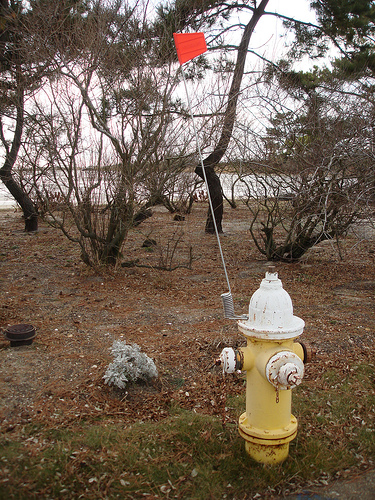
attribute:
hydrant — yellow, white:
[213, 265, 312, 464]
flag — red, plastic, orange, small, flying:
[170, 30, 237, 320]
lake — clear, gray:
[0, 166, 356, 211]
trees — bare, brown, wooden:
[1, 1, 372, 272]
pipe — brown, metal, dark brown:
[4, 324, 38, 346]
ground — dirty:
[0, 193, 373, 500]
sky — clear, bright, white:
[1, 3, 374, 170]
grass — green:
[1, 369, 374, 498]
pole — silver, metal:
[180, 64, 238, 320]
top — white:
[236, 265, 306, 338]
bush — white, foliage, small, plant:
[102, 338, 157, 389]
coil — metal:
[220, 290, 236, 321]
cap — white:
[215, 347, 235, 376]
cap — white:
[265, 349, 304, 389]